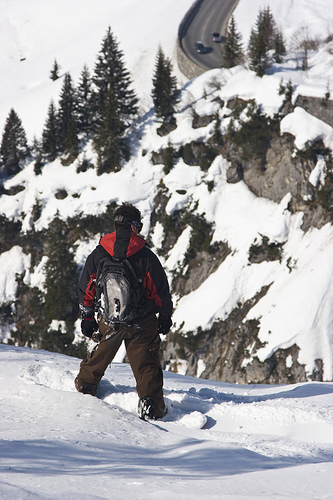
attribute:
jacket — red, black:
[81, 230, 172, 334]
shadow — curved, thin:
[173, 380, 329, 407]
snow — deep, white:
[3, 352, 329, 500]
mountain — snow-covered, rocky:
[2, 65, 330, 378]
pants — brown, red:
[77, 320, 167, 421]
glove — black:
[157, 313, 172, 332]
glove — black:
[79, 315, 98, 336]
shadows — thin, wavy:
[6, 436, 321, 478]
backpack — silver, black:
[93, 259, 144, 326]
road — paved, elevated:
[178, 3, 242, 69]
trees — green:
[61, 26, 176, 155]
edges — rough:
[151, 146, 279, 178]